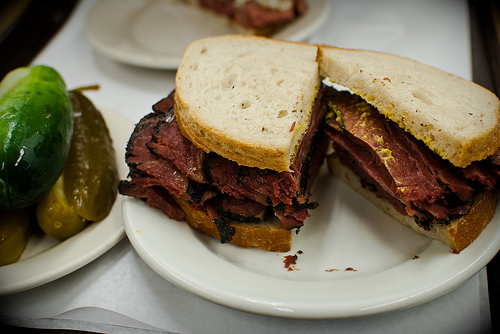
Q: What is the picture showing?
A: Food.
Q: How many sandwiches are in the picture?
A: One.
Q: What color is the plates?
A: White.